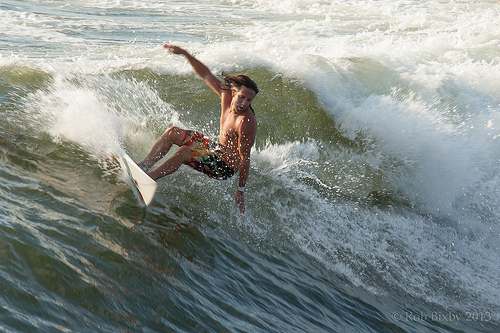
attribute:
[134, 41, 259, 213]
surfer — shirtless, open armed, looking to side, surfing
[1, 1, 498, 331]
ocean — water, calm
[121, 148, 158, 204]
surfboard — white, splashing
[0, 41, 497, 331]
wave — crested, breaking, rishing, splashing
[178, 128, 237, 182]
shorts — multi colored, colorful, colored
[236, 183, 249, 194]
watch — white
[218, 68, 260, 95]
hair — brown